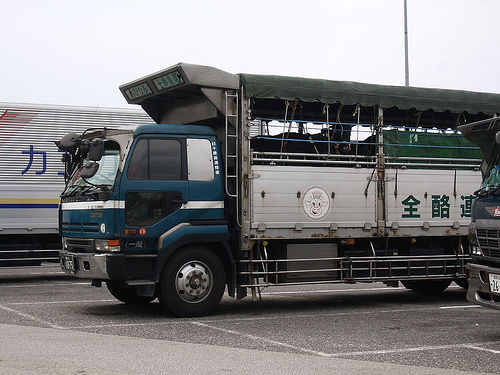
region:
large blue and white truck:
[23, 73, 491, 303]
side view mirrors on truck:
[59, 128, 116, 186]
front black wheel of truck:
[152, 242, 227, 329]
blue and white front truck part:
[38, 123, 223, 273]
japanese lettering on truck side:
[8, 141, 57, 188]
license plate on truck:
[51, 251, 78, 273]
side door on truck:
[107, 123, 207, 240]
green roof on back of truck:
[241, 73, 467, 113]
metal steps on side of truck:
[223, 240, 420, 289]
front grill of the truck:
[49, 213, 109, 253]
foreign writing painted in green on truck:
[398, 192, 459, 222]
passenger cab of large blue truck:
[53, 121, 234, 334]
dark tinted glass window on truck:
[129, 133, 189, 188]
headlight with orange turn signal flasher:
[91, 233, 124, 258]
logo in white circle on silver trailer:
[298, 184, 332, 220]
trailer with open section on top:
[247, 115, 377, 231]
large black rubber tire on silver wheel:
[156, 242, 233, 319]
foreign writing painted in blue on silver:
[13, 142, 55, 216]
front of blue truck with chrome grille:
[453, 108, 496, 336]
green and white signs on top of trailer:
[109, 65, 195, 111]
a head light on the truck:
[91, 235, 110, 253]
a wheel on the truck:
[150, 240, 234, 318]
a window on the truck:
[123, 135, 183, 182]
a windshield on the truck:
[56, 140, 124, 200]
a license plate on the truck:
[56, 252, 77, 272]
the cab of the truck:
[51, 114, 236, 316]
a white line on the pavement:
[192, 317, 327, 358]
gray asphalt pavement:
[0, 258, 498, 373]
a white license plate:
[483, 273, 499, 295]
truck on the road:
[84, 53, 487, 313]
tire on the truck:
[158, 248, 215, 320]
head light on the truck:
[97, 240, 118, 256]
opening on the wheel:
[176, 273, 186, 281]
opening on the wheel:
[190, 262, 198, 269]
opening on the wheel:
[201, 267, 213, 277]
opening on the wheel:
[200, 285, 205, 294]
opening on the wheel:
[178, 285, 186, 298]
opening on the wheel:
[190, 286, 198, 294]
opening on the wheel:
[191, 293, 201, 303]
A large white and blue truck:
[56, 60, 497, 316]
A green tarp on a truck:
[243, 70, 498, 112]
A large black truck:
[453, 115, 498, 312]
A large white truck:
[0, 98, 155, 263]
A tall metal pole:
[403, 0, 412, 87]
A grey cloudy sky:
[0, 1, 498, 139]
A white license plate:
[487, 271, 499, 291]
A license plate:
[57, 255, 77, 270]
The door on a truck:
[119, 134, 184, 248]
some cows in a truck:
[250, 128, 382, 164]